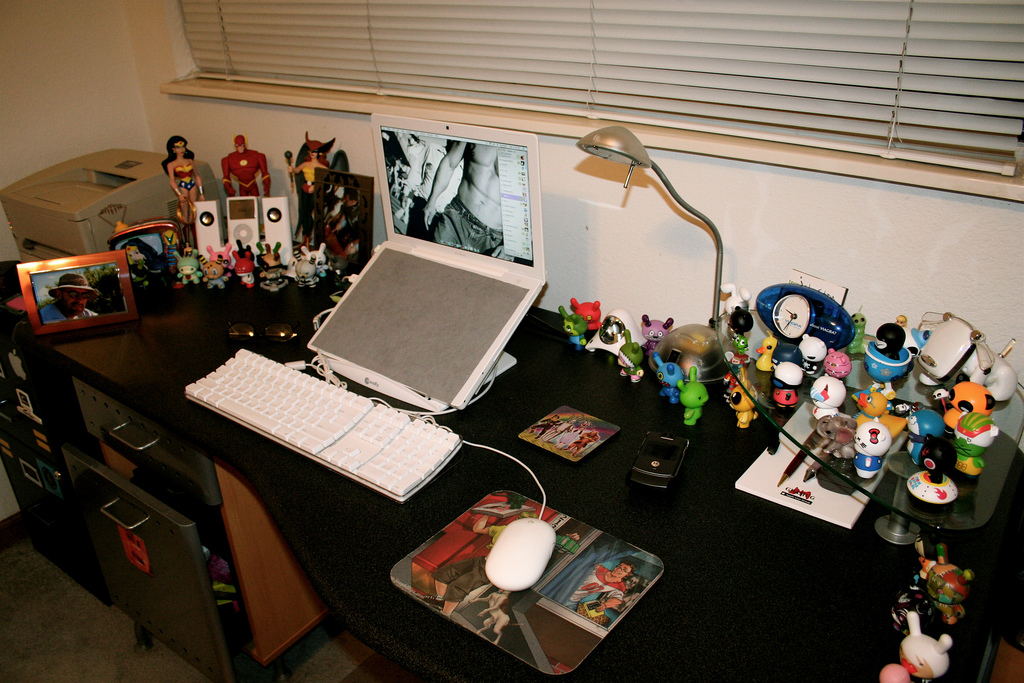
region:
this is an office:
[35, 57, 871, 551]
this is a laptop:
[315, 122, 519, 356]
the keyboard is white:
[207, 370, 420, 457]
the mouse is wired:
[462, 443, 570, 630]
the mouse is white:
[409, 525, 701, 642]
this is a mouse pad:
[386, 505, 526, 660]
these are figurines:
[646, 309, 1005, 543]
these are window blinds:
[348, 0, 927, 225]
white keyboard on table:
[190, 344, 437, 525]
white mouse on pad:
[442, 513, 563, 590]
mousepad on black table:
[437, 477, 643, 656]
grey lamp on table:
[559, 118, 765, 322]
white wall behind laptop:
[566, 219, 792, 278]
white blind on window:
[114, 0, 1019, 234]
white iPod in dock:
[189, 176, 263, 256]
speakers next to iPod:
[189, 195, 291, 265]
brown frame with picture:
[12, 218, 127, 359]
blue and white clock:
[737, 272, 839, 345]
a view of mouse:
[443, 461, 614, 649]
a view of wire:
[486, 437, 566, 492]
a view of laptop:
[242, 160, 541, 401]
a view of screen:
[391, 120, 550, 244]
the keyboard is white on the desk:
[180, 338, 465, 501]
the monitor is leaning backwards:
[306, 237, 551, 414]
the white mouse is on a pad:
[482, 514, 562, 598]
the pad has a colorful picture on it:
[376, 490, 671, 678]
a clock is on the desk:
[758, 281, 854, 357]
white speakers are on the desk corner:
[190, 192, 296, 275]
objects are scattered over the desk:
[559, 288, 1022, 680]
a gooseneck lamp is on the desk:
[575, 114, 734, 359]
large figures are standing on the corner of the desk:
[98, 127, 365, 273]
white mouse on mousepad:
[486, 511, 553, 588]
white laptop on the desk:
[321, 104, 584, 406]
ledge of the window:
[164, 69, 1021, 210]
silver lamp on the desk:
[596, 116, 734, 361]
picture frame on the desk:
[5, 241, 135, 341]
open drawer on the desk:
[59, 451, 231, 657]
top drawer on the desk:
[73, 377, 220, 517]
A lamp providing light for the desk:
[572, 121, 735, 391]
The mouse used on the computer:
[482, 512, 565, 590]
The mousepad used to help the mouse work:
[386, 486, 666, 680]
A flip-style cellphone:
[628, 426, 693, 491]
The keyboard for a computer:
[179, 339, 470, 510]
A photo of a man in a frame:
[10, 250, 147, 334]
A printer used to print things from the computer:
[0, 141, 231, 294]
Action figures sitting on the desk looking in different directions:
[549, 281, 1012, 677]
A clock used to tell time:
[755, 284, 854, 355]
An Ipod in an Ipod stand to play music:
[223, 190, 266, 255]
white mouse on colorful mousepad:
[392, 478, 664, 678]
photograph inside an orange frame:
[16, 240, 141, 340]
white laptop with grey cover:
[305, 104, 550, 411]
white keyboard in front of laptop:
[188, 104, 550, 513]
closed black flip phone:
[624, 420, 692, 491]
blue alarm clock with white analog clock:
[751, 275, 854, 353]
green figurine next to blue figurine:
[648, 337, 712, 427]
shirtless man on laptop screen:
[375, 117, 534, 277]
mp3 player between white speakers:
[181, 186, 298, 266]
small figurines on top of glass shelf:
[709, 285, 1022, 554]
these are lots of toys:
[540, 219, 1000, 581]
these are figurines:
[647, 251, 923, 410]